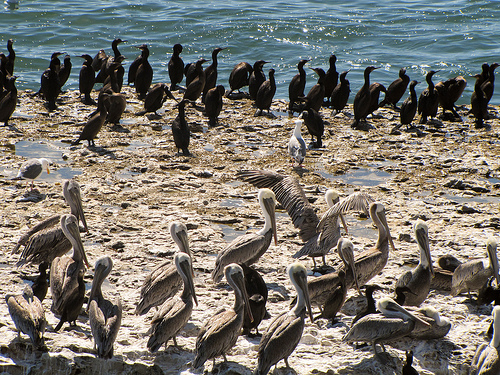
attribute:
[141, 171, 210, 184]
beach — part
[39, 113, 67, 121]
line — part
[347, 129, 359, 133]
twig — part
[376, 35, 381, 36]
water — part, calm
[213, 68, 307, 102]
pelicans — craning, turned, black, group, laying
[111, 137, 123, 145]
sand — wet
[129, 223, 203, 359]
seagull — standing, group, gray, white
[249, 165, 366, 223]
wings — extended, brown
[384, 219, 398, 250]
beak — orange